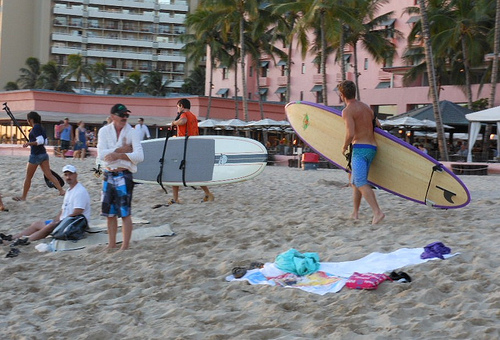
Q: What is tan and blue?
A: A surfboard.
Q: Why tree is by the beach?
A: Palm tree.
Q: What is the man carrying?
A: A surfboard with gray.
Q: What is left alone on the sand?
A: Some towels.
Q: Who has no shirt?
A: The man with blue shorts.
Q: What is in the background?
A: A pink building.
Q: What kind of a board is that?
A: A surf board.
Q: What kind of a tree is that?
A: A palm tree.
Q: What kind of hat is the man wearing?
A: A black hat.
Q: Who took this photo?
A: Jackson Mingus.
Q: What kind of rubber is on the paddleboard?
A: Gray.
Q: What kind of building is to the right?
A: A pink building.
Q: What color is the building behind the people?
A: Pink.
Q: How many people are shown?
A: 8.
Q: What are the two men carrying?
A: Surf boards.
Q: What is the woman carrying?
A: Paddles.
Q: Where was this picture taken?
A: At the beach.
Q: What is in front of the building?
A: Umbrellas.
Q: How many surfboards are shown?
A: 2.